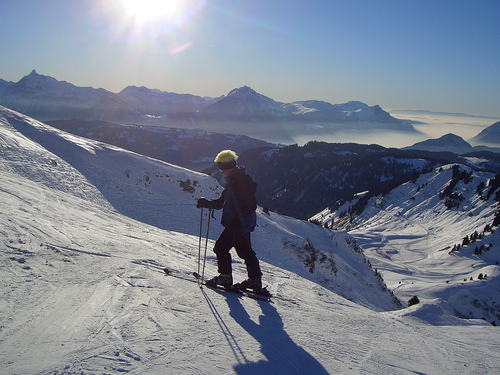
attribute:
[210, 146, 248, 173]
person in a helmet — wearing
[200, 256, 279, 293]
pair of shoes — wearing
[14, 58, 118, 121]
big mountain — covered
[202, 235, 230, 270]
black knit cap — green and black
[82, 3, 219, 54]
sun shining above — birght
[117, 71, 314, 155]
white mountain mist — thick